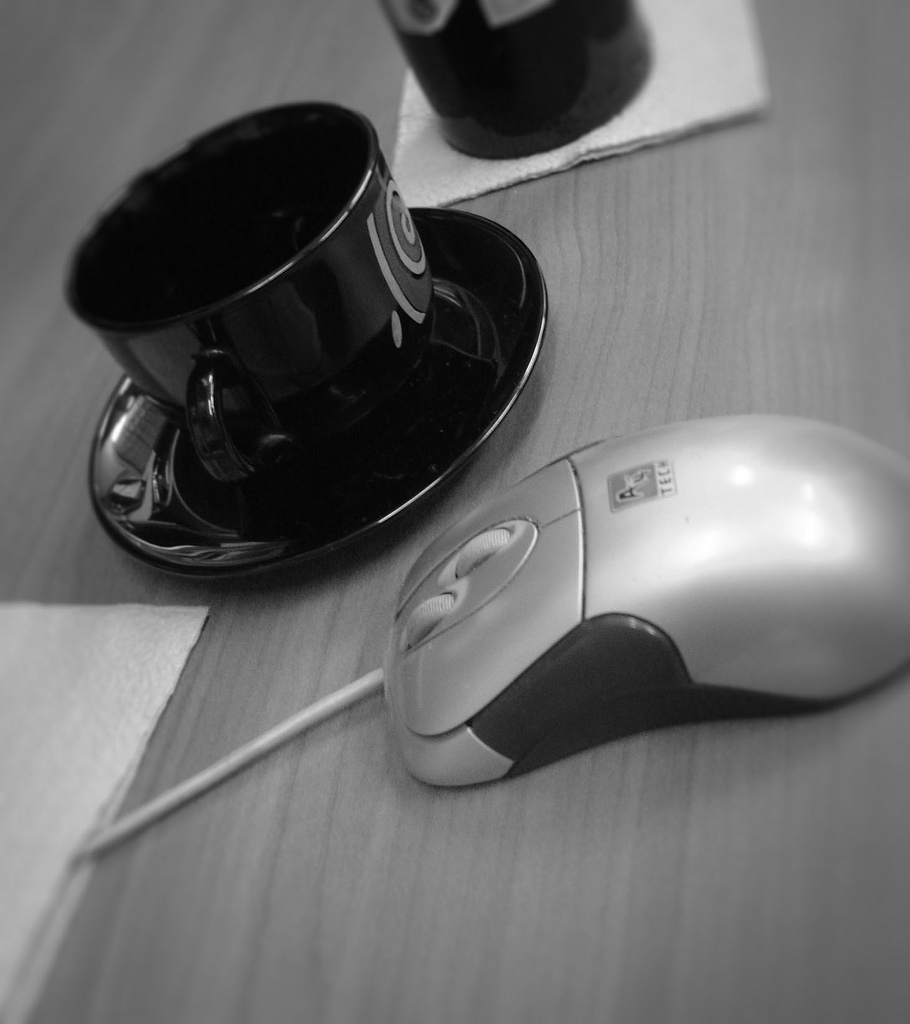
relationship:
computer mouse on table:
[384, 407, 904, 792] [0, 0, 907, 1020]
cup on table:
[58, 96, 435, 493] [0, 0, 907, 1020]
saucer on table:
[88, 206, 550, 582] [0, 0, 907, 1020]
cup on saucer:
[58, 96, 435, 493] [88, 206, 550, 582]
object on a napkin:
[385, 0, 655, 165] [392, 2, 775, 219]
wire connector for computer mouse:
[64, 668, 380, 862] [384, 407, 904, 792]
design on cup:
[355, 176, 434, 352] [58, 96, 435, 493]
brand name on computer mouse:
[603, 454, 680, 513] [384, 407, 904, 792]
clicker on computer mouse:
[392, 454, 586, 736] [384, 407, 904, 792]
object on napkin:
[385, 0, 655, 165] [392, 2, 775, 219]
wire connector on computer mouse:
[64, 668, 380, 862] [384, 407, 904, 792]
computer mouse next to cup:
[384, 407, 904, 792] [58, 96, 435, 493]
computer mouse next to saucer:
[384, 407, 904, 792] [88, 206, 550, 582]